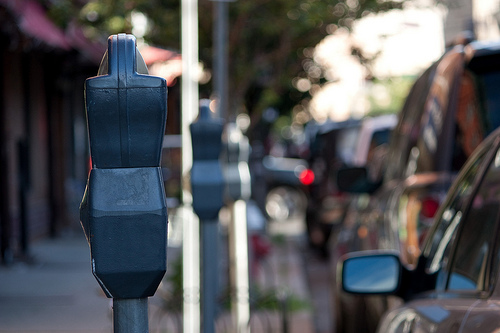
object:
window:
[439, 149, 497, 294]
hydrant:
[236, 200, 269, 291]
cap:
[242, 198, 266, 233]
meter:
[77, 32, 172, 300]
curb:
[263, 244, 323, 332]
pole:
[110, 291, 152, 333]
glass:
[334, 250, 408, 295]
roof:
[15, 0, 104, 59]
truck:
[298, 111, 397, 261]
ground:
[0, 268, 56, 298]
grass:
[208, 284, 318, 309]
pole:
[178, 4, 204, 330]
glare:
[298, 168, 316, 184]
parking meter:
[223, 119, 254, 198]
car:
[339, 123, 499, 333]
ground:
[306, 252, 326, 276]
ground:
[306, 274, 332, 299]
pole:
[196, 222, 228, 332]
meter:
[187, 96, 240, 333]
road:
[291, 29, 498, 331]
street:
[162, 170, 499, 333]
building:
[0, 0, 214, 277]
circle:
[298, 169, 314, 185]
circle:
[419, 198, 439, 218]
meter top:
[99, 32, 149, 74]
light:
[298, 168, 316, 186]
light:
[419, 198, 438, 218]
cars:
[334, 38, 499, 333]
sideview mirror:
[335, 164, 381, 196]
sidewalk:
[1, 212, 173, 332]